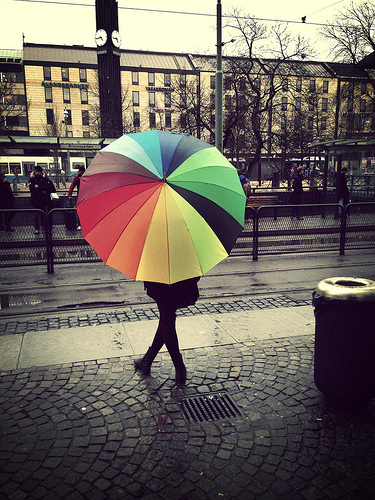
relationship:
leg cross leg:
[124, 320, 162, 387] [164, 328, 191, 385]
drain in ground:
[173, 393, 248, 422] [116, 380, 298, 487]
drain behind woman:
[173, 393, 248, 422] [101, 173, 211, 351]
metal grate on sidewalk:
[178, 391, 246, 424] [0, 291, 371, 497]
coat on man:
[26, 173, 56, 208] [26, 165, 58, 238]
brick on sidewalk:
[109, 387, 130, 402] [1, 207, 373, 496]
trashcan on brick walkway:
[310, 266, 374, 406] [0, 290, 374, 498]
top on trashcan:
[314, 274, 374, 299] [311, 275, 374, 403]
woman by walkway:
[128, 277, 204, 399] [5, 292, 370, 498]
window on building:
[43, 84, 52, 104] [0, 29, 357, 147]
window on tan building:
[131, 69, 140, 85] [16, 32, 373, 156]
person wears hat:
[24, 159, 62, 240] [32, 161, 44, 171]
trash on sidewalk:
[304, 264, 373, 404] [65, 359, 235, 484]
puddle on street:
[11, 288, 52, 316] [10, 241, 311, 329]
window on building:
[40, 66, 52, 82] [3, 42, 361, 160]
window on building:
[45, 87, 51, 103] [3, 42, 361, 160]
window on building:
[45, 106, 55, 125] [3, 42, 361, 160]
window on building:
[78, 88, 88, 103] [3, 42, 361, 160]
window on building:
[60, 87, 71, 103] [3, 42, 361, 160]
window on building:
[77, 66, 88, 82] [3, 42, 361, 160]